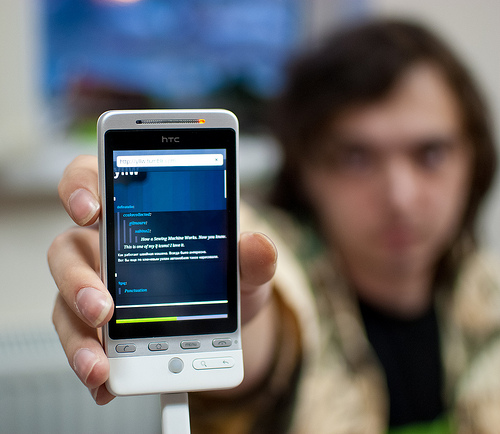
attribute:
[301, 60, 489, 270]
face — blurred, man's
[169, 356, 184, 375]
power button — foggy, translucent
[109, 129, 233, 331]
screen — blue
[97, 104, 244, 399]
cell phone — htc, white, gray, here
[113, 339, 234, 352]
row — buttons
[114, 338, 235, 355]
buttons — grey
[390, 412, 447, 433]
stripe — green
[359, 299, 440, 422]
shirt — man's, patterned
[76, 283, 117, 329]
finger nail — man's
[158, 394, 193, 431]
charging plug — white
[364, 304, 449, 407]
undershirt — black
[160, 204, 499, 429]
coat — light colored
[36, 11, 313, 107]
screen — large, blue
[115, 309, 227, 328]
download progress — green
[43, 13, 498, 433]
man — caucasian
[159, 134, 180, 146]
logo — silver, htc